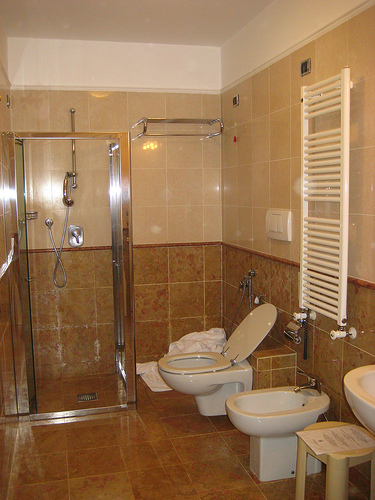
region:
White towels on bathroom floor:
[135, 359, 171, 392]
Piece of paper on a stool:
[293, 422, 372, 455]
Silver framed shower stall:
[8, 129, 137, 424]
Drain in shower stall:
[77, 390, 98, 402]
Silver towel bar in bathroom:
[126, 115, 225, 141]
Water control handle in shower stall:
[67, 224, 85, 249]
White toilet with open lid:
[153, 302, 280, 388]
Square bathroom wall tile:
[161, 164, 208, 210]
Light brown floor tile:
[113, 437, 188, 475]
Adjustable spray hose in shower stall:
[39, 166, 79, 287]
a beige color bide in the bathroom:
[225, 378, 326, 476]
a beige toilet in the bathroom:
[156, 301, 277, 396]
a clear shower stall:
[0, 129, 133, 421]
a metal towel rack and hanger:
[133, 115, 225, 139]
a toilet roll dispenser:
[281, 322, 302, 345]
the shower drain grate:
[75, 390, 97, 402]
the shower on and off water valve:
[66, 225, 83, 248]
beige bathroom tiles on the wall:
[224, 113, 299, 208]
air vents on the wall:
[298, 57, 311, 76]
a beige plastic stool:
[297, 420, 374, 498]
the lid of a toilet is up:
[145, 287, 284, 415]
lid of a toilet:
[219, 299, 282, 371]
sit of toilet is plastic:
[155, 347, 230, 379]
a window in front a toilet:
[289, 68, 353, 334]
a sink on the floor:
[219, 367, 324, 484]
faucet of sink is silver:
[287, 365, 323, 398]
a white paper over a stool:
[289, 417, 373, 498]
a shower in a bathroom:
[30, 93, 102, 298]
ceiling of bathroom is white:
[9, 2, 319, 63]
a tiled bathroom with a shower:
[3, 40, 372, 498]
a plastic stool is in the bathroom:
[292, 417, 373, 498]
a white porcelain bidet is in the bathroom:
[224, 375, 329, 482]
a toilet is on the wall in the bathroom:
[157, 302, 277, 417]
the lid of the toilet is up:
[221, 303, 276, 361]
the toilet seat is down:
[156, 348, 232, 373]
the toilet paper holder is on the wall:
[282, 315, 305, 343]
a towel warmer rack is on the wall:
[294, 66, 356, 342]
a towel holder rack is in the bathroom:
[128, 114, 222, 140]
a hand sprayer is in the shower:
[42, 107, 80, 289]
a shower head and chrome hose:
[43, 167, 79, 288]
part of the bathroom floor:
[7, 418, 185, 497]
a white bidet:
[224, 368, 326, 484]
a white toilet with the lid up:
[156, 300, 280, 421]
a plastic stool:
[292, 416, 373, 498]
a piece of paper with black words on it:
[296, 422, 372, 458]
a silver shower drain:
[76, 391, 100, 402]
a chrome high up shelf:
[131, 115, 224, 141]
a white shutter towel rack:
[297, 65, 354, 328]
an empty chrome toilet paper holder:
[282, 316, 303, 348]